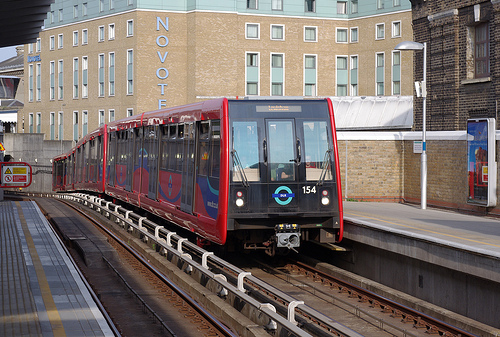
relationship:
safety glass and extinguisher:
[231, 113, 368, 200] [223, 145, 328, 212]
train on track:
[29, 87, 363, 271] [167, 261, 499, 336]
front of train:
[225, 97, 343, 254] [29, 87, 363, 271]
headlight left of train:
[228, 190, 250, 207] [86, 88, 353, 245]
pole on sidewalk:
[396, 40, 429, 215] [341, 196, 498, 253]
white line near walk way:
[27, 192, 115, 334] [2, 196, 119, 334]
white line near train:
[27, 192, 115, 334] [29, 87, 363, 271]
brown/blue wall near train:
[21, 0, 414, 99] [56, 97, 342, 244]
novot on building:
[153, 15, 173, 112] [30, 11, 440, 201]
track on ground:
[243, 264, 483, 334] [18, 237, 492, 327]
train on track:
[29, 87, 363, 271] [243, 264, 483, 334]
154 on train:
[297, 182, 322, 197] [29, 87, 363, 271]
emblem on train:
[268, 184, 300, 208] [45, 102, 363, 264]